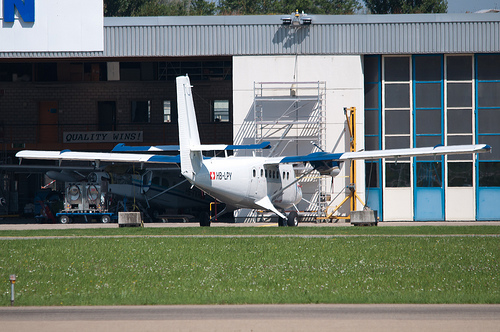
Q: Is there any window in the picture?
A: Yes, there are windows.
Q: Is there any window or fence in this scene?
A: Yes, there are windows.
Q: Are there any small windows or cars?
A: Yes, there are small windows.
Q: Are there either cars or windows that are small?
A: Yes, the windows are small.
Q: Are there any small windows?
A: Yes, there are small windows.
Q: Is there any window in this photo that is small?
A: Yes, there are windows that are small.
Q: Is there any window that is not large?
A: Yes, there are small windows.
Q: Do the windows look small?
A: Yes, the windows are small.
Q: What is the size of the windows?
A: The windows are small.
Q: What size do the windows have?
A: The windows have small size.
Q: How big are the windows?
A: The windows are small.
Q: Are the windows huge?
A: No, the windows are small.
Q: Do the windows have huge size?
A: No, the windows are small.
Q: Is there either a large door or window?
A: No, there are windows but they are small.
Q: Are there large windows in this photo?
A: No, there are windows but they are small.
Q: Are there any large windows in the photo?
A: No, there are windows but they are small.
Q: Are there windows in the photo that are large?
A: No, there are windows but they are small.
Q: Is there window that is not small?
A: No, there are windows but they are small.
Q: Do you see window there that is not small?
A: No, there are windows but they are small.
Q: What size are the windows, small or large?
A: The windows are small.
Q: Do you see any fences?
A: No, there are no fences.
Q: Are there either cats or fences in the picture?
A: No, there are no fences or cats.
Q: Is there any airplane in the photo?
A: Yes, there is an airplane.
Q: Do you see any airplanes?
A: Yes, there is an airplane.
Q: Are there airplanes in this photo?
A: Yes, there is an airplane.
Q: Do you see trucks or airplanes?
A: Yes, there is an airplane.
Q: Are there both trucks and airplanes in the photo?
A: No, there is an airplane but no trucks.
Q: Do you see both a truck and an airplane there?
A: No, there is an airplane but no trucks.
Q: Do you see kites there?
A: No, there are no kites.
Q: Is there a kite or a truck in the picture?
A: No, there are no kites or trucks.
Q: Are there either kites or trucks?
A: No, there are no kites or trucks.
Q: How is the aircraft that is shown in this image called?
A: The aircraft is an airplane.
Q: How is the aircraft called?
A: The aircraft is an airplane.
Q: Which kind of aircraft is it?
A: The aircraft is an airplane.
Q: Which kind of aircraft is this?
A: This is an airplane.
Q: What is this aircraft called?
A: This is an airplane.